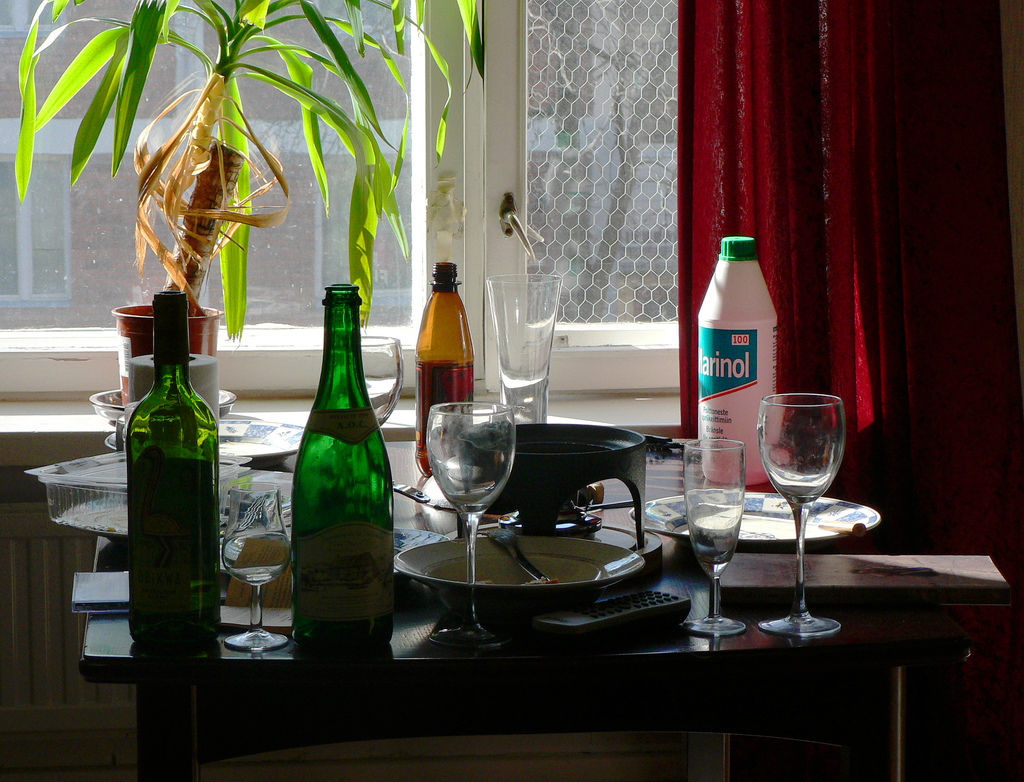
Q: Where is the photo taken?
A: In a dining room.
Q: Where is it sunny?
A: In a restaurant.